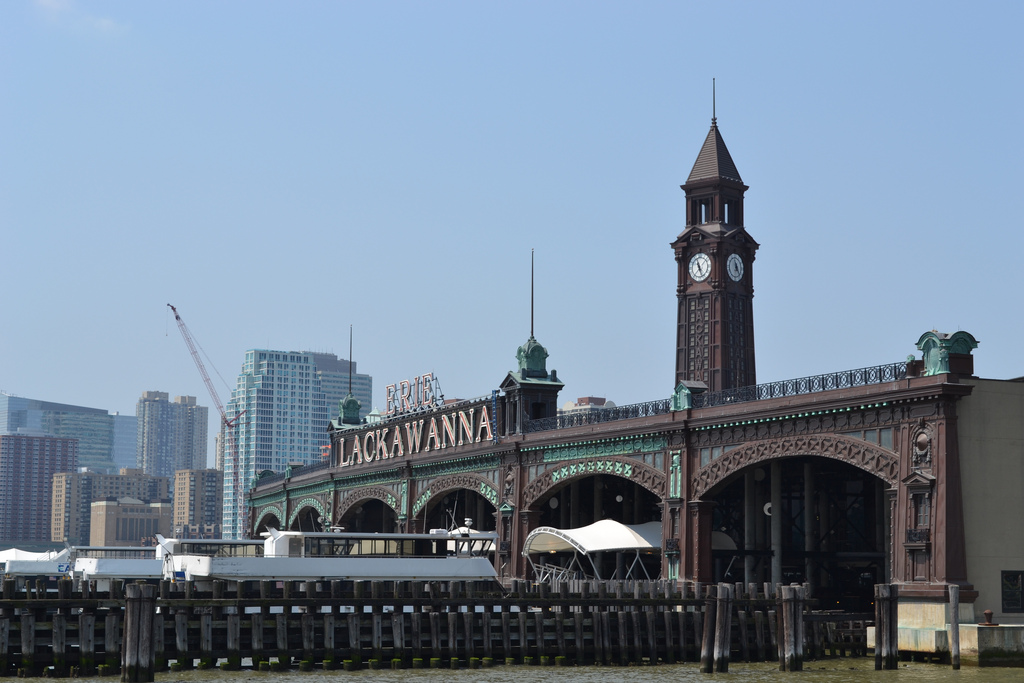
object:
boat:
[521, 518, 738, 581]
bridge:
[246, 78, 1024, 669]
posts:
[874, 584, 896, 670]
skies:
[0, 0, 1021, 473]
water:
[0, 649, 1024, 683]